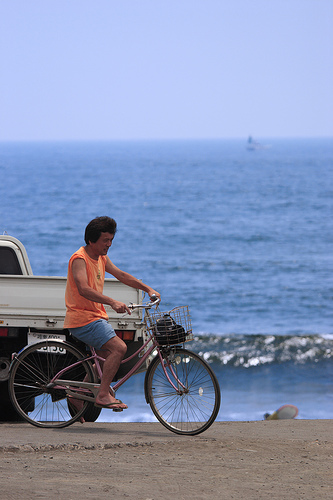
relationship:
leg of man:
[97, 354, 130, 403] [55, 207, 157, 427]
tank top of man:
[66, 259, 102, 318] [55, 207, 157, 427]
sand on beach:
[241, 430, 261, 442] [5, 449, 311, 497]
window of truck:
[5, 269, 29, 276] [53, 295, 123, 345]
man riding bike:
[55, 207, 157, 427] [0, 308, 220, 432]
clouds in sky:
[11, 29, 108, 65] [197, 3, 233, 39]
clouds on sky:
[11, 29, 108, 65] [197, 3, 233, 39]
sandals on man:
[91, 397, 129, 418] [55, 207, 157, 427]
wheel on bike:
[143, 349, 202, 438] [0, 308, 220, 432]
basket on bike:
[138, 305, 189, 342] [0, 308, 220, 432]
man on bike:
[55, 207, 157, 427] [0, 308, 220, 432]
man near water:
[55, 207, 157, 427] [201, 185, 248, 255]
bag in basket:
[154, 316, 171, 334] [138, 305, 189, 342]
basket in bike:
[138, 305, 189, 342] [0, 308, 220, 432]